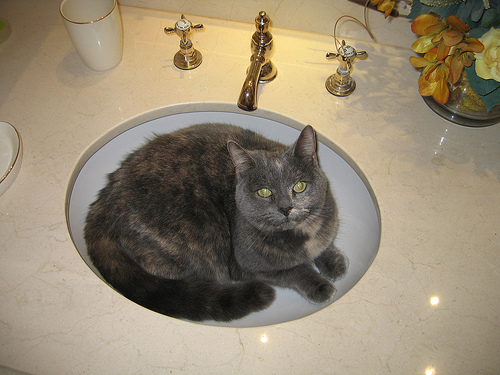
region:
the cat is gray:
[62, 115, 352, 325]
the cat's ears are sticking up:
[213, 120, 325, 178]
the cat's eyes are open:
[235, 175, 316, 199]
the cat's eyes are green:
[250, 177, 316, 199]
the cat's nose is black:
[273, 206, 297, 214]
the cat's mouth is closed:
[266, 216, 303, 231]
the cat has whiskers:
[255, 207, 338, 247]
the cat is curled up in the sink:
[48, 95, 395, 337]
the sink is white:
[50, 106, 396, 338]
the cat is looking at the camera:
[59, 110, 359, 325]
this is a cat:
[96, 131, 330, 278]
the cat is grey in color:
[96, 141, 331, 265]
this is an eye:
[293, 182, 308, 197]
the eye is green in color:
[291, 178, 309, 192]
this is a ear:
[288, 120, 315, 157]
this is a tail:
[144, 260, 205, 308]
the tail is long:
[171, 276, 274, 318]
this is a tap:
[223, 15, 281, 115]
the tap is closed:
[231, 15, 276, 107]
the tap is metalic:
[228, 13, 281, 110]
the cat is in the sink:
[68, 112, 365, 328]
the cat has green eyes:
[244, 182, 315, 202]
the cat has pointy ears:
[215, 126, 329, 175]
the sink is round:
[43, 100, 402, 334]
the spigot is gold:
[232, 8, 283, 120]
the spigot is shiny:
[225, 7, 280, 114]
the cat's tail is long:
[80, 190, 273, 320]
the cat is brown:
[62, 114, 355, 321]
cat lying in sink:
[97, 111, 383, 311]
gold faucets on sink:
[170, 13, 366, 113]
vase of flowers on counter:
[397, 1, 490, 122]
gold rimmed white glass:
[47, 5, 157, 73]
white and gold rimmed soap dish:
[3, 107, 28, 202]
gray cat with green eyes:
[216, 133, 351, 283]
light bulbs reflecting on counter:
[388, 260, 458, 372]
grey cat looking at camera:
[143, 113, 395, 313]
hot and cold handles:
[160, 10, 360, 87]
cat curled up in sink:
[77, 97, 386, 324]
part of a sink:
[409, 239, 472, 307]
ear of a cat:
[227, 136, 253, 181]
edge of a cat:
[273, 309, 304, 330]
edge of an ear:
[292, 127, 318, 159]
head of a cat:
[254, 143, 294, 175]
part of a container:
[444, 74, 481, 118]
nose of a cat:
[281, 196, 297, 228]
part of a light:
[431, 295, 442, 310]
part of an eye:
[255, 178, 270, 198]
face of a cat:
[247, 176, 302, 240]